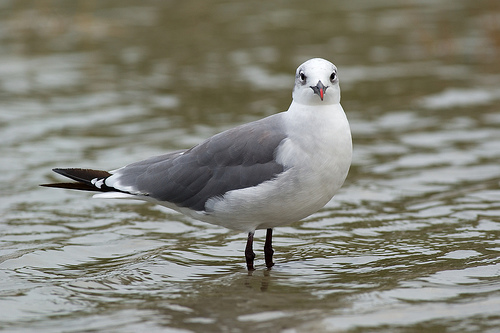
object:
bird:
[37, 56, 354, 271]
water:
[1, 0, 499, 333]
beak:
[313, 87, 326, 101]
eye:
[299, 72, 306, 82]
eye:
[330, 72, 335, 80]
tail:
[38, 167, 114, 193]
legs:
[244, 227, 275, 272]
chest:
[283, 105, 351, 230]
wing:
[117, 121, 276, 199]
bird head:
[293, 57, 341, 104]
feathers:
[92, 167, 142, 201]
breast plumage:
[205, 104, 352, 234]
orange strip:
[319, 88, 324, 101]